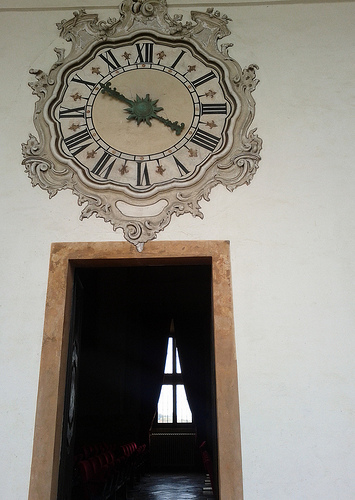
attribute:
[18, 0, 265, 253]
clock — beige, ancient, gold, small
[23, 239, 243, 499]
door — brown, wood, large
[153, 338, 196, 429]
window — shining, open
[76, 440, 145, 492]
seats — red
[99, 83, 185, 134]
hands — old, antique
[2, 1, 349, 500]
walls — white, gray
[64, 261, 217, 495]
room — dark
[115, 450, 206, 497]
floor — shiny, tile